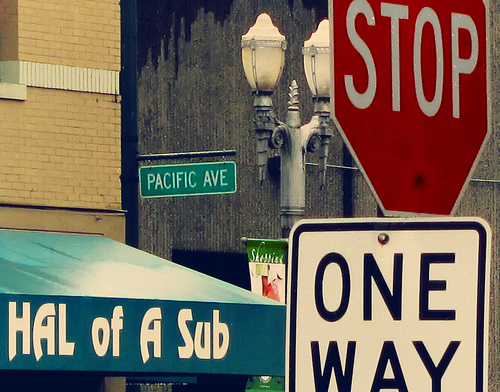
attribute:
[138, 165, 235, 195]
sign — PACIFIC AVE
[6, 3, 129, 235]
building — tan, brick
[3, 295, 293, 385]
sign — business, name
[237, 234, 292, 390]
banner — is white, is green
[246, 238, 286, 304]
banner — street, pole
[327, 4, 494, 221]
sign — STOP, traffic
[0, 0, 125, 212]
brick wall — tan 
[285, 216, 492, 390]
sign — black, white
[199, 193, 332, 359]
green banner — is green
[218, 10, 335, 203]
street light — overhead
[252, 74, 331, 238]
lamp post — is metal, is gray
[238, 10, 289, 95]
light — overhead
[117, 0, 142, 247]
pole — is metal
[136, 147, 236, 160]
pole — metal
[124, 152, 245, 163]
pole — metal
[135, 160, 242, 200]
sign — white 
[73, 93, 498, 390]
business —  green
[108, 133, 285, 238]
sign — green, white, street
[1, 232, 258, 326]
awning — blue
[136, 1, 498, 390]
building — is black